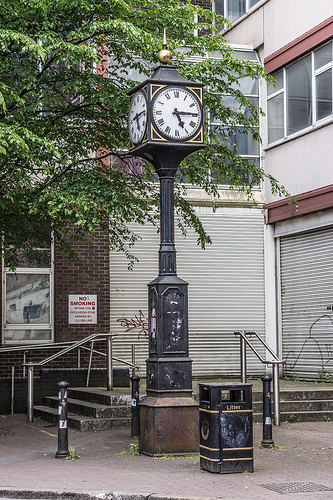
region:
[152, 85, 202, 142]
white clock on post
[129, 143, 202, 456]
black iron clock post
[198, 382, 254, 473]
black metal trash can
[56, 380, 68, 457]
black post in ground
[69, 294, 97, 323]
white sign on wall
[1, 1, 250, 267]
tree with green leaves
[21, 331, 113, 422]
grey metal railing on steps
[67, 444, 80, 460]
weed growing in ground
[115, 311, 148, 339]
red graffiti on wall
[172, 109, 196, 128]
black hands on clock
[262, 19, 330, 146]
red frame over window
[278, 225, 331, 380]
metal door with ridges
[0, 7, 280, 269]
green leaves on tree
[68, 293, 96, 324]
red and white sign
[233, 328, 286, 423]
metal railing over stairs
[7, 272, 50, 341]
reflection on window surface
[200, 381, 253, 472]
black and gold garbage can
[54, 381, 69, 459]
black post with stickers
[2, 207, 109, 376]
brick wall of building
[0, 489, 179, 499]
broken edge of curb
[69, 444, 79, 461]
leaves near the pole.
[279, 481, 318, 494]
grate on the sidewalk.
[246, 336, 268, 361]
railing near the steps.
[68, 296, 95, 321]
sign on the wall.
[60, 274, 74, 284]
wall made of brick.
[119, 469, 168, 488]
sidewalk made of brick.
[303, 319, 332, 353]
graffiti on the wall.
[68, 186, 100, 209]
leaves on the tree.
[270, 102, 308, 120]
windows on the building.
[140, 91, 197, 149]
clock on the pole.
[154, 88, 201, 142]
clock face on a clock tower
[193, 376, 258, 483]
black trash can on a city street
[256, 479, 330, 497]
grate on the sidewalk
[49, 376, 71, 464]
black pole with stickers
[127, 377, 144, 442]
black pole with stickers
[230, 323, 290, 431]
metal bannister on stairs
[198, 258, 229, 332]
metal rolling door on a store front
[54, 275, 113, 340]
red and white no smoking sign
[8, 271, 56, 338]
reflections on a window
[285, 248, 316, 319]
metal rolling door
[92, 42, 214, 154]
two clocks are showing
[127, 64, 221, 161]
the face of the clock is white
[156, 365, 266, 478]
the garbage can is square shaped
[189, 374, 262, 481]
the garbage can is black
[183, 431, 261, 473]
gold lines on the garbage can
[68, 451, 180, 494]
the ground is made of bricks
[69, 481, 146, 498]
the curb is broken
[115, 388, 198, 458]
the base of the clock is rusty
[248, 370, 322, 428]
three steps under the clock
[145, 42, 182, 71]
a gold ball on top of the clock